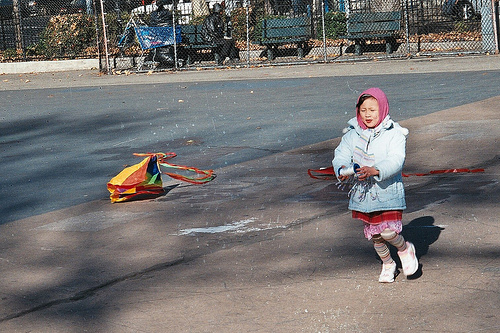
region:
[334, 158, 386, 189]
hands holding spool of twine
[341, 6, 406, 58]
bench behind a chain link fence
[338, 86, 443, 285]
person casting short shadow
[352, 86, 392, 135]
woman's head with pink hood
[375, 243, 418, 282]
pair of white shoes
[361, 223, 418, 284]
white shoes and striped leggings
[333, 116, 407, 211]
light blue winter coat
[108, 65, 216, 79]
dried leaves on ground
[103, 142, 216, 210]
kite crashed to ground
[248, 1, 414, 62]
two benches behind a fence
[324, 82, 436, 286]
child walking on sidewalk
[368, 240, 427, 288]
pair of child sized sneakers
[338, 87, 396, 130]
pink jacket hood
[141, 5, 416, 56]
three green wooden benches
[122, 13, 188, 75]
blue shopping cart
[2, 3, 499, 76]
tall metal fence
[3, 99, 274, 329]
black shadows on street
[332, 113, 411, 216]
blue coat on child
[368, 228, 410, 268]
striped multi-color stocking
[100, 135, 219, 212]
red and yellow kite on ground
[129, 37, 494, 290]
a girl on the road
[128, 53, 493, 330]
a girl running on the road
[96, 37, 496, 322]
a girl running on the street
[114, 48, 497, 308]
a girl flying a kite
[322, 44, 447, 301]
a girl wearing a blue jacket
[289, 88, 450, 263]
a girl wearing a jacket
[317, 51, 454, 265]
a girl wearing a hood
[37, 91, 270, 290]
a kite close to the ground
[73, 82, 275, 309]
a different color kite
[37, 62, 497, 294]
a kite and a girl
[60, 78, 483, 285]
she is trying to fly a kite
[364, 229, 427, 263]
she has brightly colored socks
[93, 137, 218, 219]
a colorful kite on the ground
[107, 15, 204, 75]
a blue shopping cart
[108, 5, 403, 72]
wooden green benches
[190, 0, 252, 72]
a person sitting on the bench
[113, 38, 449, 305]
a girl playing in the park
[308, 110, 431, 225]
she is wearing a blue jacket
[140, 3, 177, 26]
a black garbage bag in the cart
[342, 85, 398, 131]
her hood is pink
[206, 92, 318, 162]
Road is grey color.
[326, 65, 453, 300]
One girl is standing in road.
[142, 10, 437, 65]
Bench is green color.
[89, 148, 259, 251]
Kite is in road.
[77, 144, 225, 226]
Kite is yellow and red color.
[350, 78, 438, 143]
girl is wearing pink cap.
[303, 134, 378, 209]
Girl is holding white thread.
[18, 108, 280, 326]
Shadow is in road.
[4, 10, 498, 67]
Fence is behind the girl.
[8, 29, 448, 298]
Day time picture.